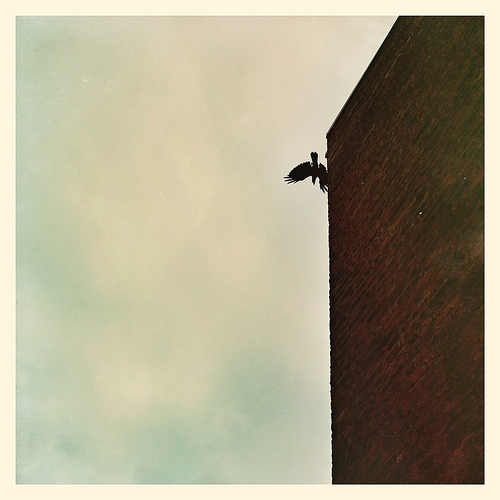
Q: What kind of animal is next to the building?
A: A pigeon.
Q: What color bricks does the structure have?
A: Red.